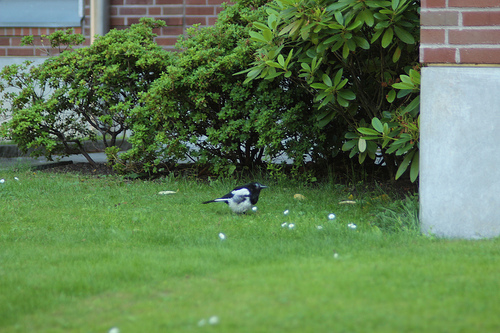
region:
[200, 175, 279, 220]
fat bird sitting in grass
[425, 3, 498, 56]
brick outside of a building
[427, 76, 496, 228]
concrete base of a building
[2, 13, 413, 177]
green bushes lining path outside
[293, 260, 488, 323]
smooth, green grass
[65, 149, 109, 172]
dirt underneath a bush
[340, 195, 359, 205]
a leaf that has fallen off of a bush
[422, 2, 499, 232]
corner of a building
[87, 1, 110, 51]
metal pipe attached to building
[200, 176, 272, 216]
black and white bird in grass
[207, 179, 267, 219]
black and white bird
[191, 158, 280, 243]
bird standing on grass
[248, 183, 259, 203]
black head and neck of bird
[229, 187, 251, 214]
white body of bird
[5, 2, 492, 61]
red brick wall of building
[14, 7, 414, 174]
bushes behind black and white bird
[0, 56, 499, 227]
cement foundation of building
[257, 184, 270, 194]
peak of black and white bird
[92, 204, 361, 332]
white flowers in grass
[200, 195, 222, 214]
black tail feathers of bird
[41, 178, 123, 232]
this is the grass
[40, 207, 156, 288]
the grass is green in color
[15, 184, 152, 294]
the grass is short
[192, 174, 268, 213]
this is a bird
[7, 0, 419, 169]
these are some trees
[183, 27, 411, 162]
the trees are tall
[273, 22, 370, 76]
the leaves are green in color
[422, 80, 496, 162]
the wall is white in color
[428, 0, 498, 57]
the wall is made of bricks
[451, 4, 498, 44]
the bricks are brown in color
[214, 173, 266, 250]
Black and white bird standing in grass.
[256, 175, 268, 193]
Bird has black beak.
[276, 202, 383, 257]
White weeds in grass.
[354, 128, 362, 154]
Green leaves on plant.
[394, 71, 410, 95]
Green leaves on plant.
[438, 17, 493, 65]
Red and brown brick building.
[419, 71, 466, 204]
Bottom part of building is concrete.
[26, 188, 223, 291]
Grass on ground is green.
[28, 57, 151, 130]
Green bush near building.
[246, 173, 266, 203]
Bird has black head.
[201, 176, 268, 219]
a bird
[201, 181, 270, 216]
a black and white bird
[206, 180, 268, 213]
the bird has a white belly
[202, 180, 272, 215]
the bird has a round body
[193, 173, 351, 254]
the bird is on the grass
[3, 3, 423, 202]
bushes are behind the bird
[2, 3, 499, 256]
a house is behind the bird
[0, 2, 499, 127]
the building has brick walls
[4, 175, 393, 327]
small white flowers in the grass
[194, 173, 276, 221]
the bird is on the ground